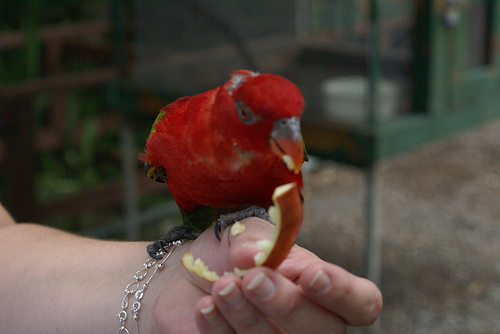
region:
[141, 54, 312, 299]
a red bird eating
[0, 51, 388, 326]
a red bird being fed from a person's hand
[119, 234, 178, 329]
a silver link bracelet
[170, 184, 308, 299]
a strip of red apple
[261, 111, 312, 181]
a bird's beak with food in it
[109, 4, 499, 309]
a green bird cage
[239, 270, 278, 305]
a polished finger nail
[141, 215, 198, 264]
a bird's claw foot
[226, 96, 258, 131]
a bird's right eye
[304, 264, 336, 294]
a polished finger nail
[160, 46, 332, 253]
red bird on person's hand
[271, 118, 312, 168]
orange and gray beak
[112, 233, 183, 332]
silver bracelet on hand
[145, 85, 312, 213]
bird with many colors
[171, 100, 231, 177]
red feathers on bird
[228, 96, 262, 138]
eye of a bird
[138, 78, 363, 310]
bird eating something out of hanfd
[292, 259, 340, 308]
finger of person feeding bird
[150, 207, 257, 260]
talons of the bird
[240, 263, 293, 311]
fingernail of person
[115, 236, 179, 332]
Bracelet around the wrist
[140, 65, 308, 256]
Red bird on wrist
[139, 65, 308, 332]
Bird eating fruit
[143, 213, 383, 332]
Fingernails on hand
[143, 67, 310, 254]
Food in bird's beak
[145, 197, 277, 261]
Black bird claws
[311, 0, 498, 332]
Bowl in bird cage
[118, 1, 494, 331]
Green bird cage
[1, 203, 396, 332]
Arm with silver bracelet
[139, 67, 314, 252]
Red feathers on bird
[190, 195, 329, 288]
apple skin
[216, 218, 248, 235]
a bit of apple on a hand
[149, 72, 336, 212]
a red bird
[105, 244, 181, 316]
a pair of silver bracelets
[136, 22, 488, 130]
a bird cage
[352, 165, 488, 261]
mulch on the ground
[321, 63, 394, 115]
bowl in the bird cage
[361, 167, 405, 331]
a support leg for the cage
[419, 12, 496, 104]
the door to the cage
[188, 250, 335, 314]
manicured fingernails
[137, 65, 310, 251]
a bird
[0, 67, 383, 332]
a bird sitting on a hand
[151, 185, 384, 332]
a hand holding an apple piece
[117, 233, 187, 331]
an arm with a silver bracelet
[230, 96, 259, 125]
one bird's eye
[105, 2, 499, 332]
bird cage behind bird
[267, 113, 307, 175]
bird's beak is black and red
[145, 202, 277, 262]
the bird's feet are black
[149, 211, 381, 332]
five fingers on hand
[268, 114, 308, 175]
piece of apple in bird's beak